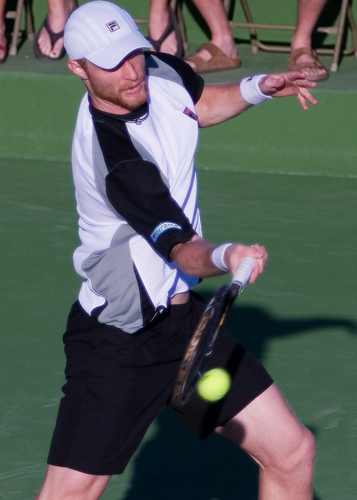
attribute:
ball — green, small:
[200, 360, 240, 405]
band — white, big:
[236, 70, 272, 109]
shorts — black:
[61, 322, 254, 445]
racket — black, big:
[166, 277, 270, 409]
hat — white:
[65, 6, 160, 65]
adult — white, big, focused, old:
[49, 12, 307, 480]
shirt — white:
[78, 110, 227, 300]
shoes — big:
[182, 30, 335, 93]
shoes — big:
[34, 19, 68, 56]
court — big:
[2, 50, 324, 497]